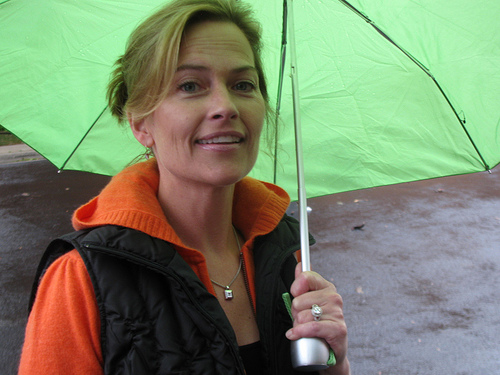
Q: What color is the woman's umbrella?
A: Green.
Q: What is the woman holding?
A: Umbrella.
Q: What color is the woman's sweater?
A: Orange.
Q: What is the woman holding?
A: A green umbrella.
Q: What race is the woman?
A: Caucasian.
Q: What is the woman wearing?
A: Red sweater and black vest.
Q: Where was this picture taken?
A: A street.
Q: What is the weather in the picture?
A: Raining.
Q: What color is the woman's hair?
A: Blonde.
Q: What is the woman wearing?
A: Jewelry.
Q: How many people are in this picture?
A: One woman.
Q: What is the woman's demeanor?
A: Happy.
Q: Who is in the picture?
A: A woman.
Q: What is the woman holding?
A: A umbrella.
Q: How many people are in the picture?
A: 1.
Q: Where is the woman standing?
A: In a street.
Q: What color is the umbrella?
A: Green.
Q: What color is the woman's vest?
A: Black.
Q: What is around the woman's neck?
A: A necklace.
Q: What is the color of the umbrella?
A: Light green.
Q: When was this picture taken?
A: During the day.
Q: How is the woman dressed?
A: In a vest and hoodie.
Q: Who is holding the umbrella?
A: A young woman.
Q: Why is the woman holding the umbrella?
A: It is raining.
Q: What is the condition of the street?
A: Wet.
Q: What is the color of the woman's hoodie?
A: Orange.